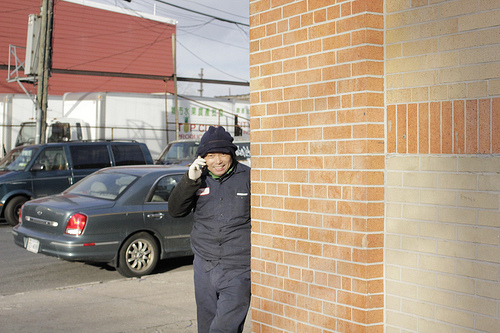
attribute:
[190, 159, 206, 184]
glove — white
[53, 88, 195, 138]
wall — white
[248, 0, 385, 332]
pillar — brown, brick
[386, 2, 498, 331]
wall — beige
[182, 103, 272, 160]
cap — black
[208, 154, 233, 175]
face — smiling